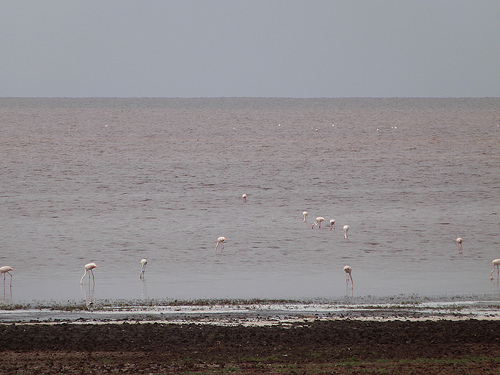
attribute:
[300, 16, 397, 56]
clouds — fluffy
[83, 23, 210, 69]
sky — light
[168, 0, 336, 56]
sky — light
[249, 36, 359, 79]
clouds — fluffy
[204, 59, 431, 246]
birds — many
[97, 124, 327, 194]
ocean — calm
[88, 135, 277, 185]
ocean — deep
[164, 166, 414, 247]
birds — many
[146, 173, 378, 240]
birds — many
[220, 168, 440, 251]
birds — numerous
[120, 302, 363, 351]
ground — nearby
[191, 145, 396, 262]
birds — white